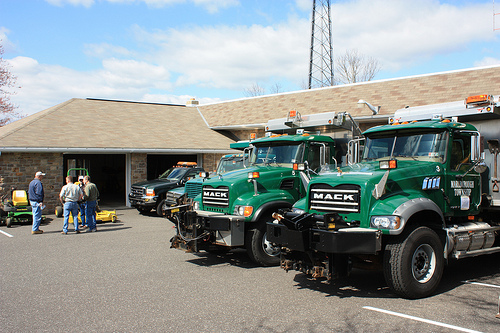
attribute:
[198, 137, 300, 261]
truck — parked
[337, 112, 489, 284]
truck — parked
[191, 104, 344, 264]
truck — large , green 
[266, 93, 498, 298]
truck — green, large , parked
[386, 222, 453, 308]
wheel — black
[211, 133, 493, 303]
trucks — green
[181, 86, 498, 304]
trucks — green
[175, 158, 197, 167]
light bar — orange 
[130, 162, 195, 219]
truck — black ,  pick up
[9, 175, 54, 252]
equipment — John Deere ,  lawn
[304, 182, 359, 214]
emblem — mack 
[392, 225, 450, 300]
black tire — Large ,  black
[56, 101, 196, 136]
roof — beige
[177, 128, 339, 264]
green truck — big ,  green ,  mack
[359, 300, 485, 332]
line — white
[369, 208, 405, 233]
lights — white, orange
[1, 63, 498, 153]
roof — beige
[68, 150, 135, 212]
door — garage 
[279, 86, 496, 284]
truck — parked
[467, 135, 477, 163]
mirror — large , side view 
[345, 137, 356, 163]
mirror — large , side view 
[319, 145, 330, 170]
mirror — large , side view 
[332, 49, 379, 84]
tree — Winter ,  bare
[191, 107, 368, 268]
pick up — green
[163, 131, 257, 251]
truck — mack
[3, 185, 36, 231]
mower — green , yellow 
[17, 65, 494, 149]
roof — beige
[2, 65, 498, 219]
building — large, work building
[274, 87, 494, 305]
truck — parked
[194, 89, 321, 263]
truck — parked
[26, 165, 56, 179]
cap —  white ,  baseball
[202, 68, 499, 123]
roof — beige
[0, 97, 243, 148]
roof — beige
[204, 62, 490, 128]
roof — beige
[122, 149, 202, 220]
pick up — black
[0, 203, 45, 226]
mower — lawn